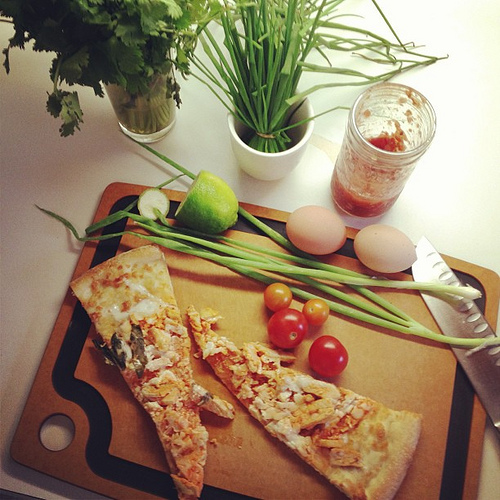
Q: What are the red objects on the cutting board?
A: Cherry tomatoes.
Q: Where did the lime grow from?
A: A tree.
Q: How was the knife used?
A: To cut food.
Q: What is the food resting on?
A: A cutting board.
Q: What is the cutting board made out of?
A: Wood.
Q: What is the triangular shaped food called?
A: Pizza.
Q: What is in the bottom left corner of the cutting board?
A: A hole.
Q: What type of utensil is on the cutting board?
A: A knife.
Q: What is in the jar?
A: Salsa.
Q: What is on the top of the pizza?
A: Cheese and meat.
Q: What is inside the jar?
A: A salsa.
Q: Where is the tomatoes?
A: Beside the pizza.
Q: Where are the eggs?
A: Beside the chives.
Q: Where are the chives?
A: Beside the eggs.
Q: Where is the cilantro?
A: In the clear vase.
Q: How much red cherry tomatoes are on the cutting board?
A: Two.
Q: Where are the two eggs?
A: On the cutting board.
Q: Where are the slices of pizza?
A: On the board.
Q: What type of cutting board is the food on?
A: Wooden.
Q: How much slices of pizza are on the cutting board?
A: Two.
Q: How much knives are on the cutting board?
A: One.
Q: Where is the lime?
A: On the cutting board.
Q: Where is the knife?
A: On the cutting board.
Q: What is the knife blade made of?
A: Metal.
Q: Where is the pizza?
A: On the cutting board.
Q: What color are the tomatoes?
A: Red.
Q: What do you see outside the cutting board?
A: Cilantro, green onions, salsa.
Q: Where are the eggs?
A: Next to green onions.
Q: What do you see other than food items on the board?
A: Knife.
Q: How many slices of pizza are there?
A: 2.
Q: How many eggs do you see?
A: Two.